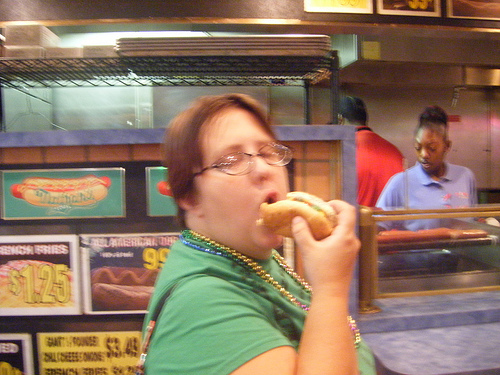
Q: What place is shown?
A: It is a restaurant.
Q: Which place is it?
A: It is a restaurant.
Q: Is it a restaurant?
A: Yes, it is a restaurant.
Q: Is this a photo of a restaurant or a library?
A: It is showing a restaurant.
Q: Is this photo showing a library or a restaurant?
A: It is showing a restaurant.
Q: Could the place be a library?
A: No, it is a restaurant.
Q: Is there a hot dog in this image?
A: Yes, there is a hot dog.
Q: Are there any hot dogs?
A: Yes, there is a hot dog.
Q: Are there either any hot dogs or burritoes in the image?
A: Yes, there is a hot dog.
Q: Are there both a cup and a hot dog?
A: No, there is a hot dog but no cups.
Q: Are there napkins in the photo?
A: No, there are no napkins.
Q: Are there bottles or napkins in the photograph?
A: No, there are no napkins or bottles.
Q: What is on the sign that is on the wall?
A: The hot dog is on the sign.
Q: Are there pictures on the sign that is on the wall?
A: No, there is a hot dog on the sign.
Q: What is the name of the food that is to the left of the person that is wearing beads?
A: The food is a hot dog.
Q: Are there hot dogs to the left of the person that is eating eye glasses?
A: Yes, there is a hot dog to the left of the person.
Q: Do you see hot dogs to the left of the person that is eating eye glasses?
A: Yes, there is a hot dog to the left of the person.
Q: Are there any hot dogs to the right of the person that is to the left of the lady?
A: No, the hot dog is to the left of the person.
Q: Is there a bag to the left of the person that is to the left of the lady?
A: No, there is a hot dog to the left of the person.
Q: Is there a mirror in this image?
A: No, there are no mirrors.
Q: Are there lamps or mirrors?
A: No, there are no mirrors or lamps.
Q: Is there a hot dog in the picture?
A: Yes, there is a hot dog.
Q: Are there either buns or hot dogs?
A: Yes, there is a hot dog.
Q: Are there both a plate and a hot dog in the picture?
A: No, there is a hot dog but no plates.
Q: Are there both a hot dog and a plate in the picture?
A: No, there is a hot dog but no plates.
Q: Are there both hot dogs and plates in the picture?
A: No, there is a hot dog but no plates.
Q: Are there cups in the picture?
A: No, there are no cups.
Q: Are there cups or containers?
A: No, there are no cups or containers.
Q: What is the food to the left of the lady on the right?
A: The food is a hot dog.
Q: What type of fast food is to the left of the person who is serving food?
A: The food is a hot dog.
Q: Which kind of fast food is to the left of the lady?
A: The food is a hot dog.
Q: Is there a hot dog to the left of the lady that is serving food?
A: Yes, there is a hot dog to the left of the lady.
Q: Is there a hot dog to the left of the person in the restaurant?
A: Yes, there is a hot dog to the left of the lady.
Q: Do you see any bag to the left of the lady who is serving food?
A: No, there is a hot dog to the left of the lady.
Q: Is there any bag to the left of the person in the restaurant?
A: No, there is a hot dog to the left of the lady.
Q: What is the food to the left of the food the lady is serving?
A: The food is a hot dog.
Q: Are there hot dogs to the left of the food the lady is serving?
A: Yes, there is a hot dog to the left of the food.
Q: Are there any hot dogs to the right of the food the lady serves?
A: No, the hot dog is to the left of the food.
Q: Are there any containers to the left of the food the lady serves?
A: No, there is a hot dog to the left of the food.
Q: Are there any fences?
A: No, there are no fences.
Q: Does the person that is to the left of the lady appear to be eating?
A: Yes, the person is eating.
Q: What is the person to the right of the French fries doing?
A: The person is eating.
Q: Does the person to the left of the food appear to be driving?
A: No, the person is eating.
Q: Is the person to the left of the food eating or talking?
A: The person is eating.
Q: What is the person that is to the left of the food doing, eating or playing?
A: The person is eating.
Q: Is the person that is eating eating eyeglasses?
A: Yes, the person is eating eyeglasses.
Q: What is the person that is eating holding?
A: The person is holding the hot dog.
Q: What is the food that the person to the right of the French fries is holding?
A: The food is a hot dog.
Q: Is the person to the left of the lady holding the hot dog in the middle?
A: Yes, the person is holding the hot dog.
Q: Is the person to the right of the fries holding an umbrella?
A: No, the person is holding the hot dog.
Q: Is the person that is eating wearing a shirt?
A: Yes, the person is wearing a shirt.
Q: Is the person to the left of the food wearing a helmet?
A: No, the person is wearing a shirt.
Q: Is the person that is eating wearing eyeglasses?
A: Yes, the person is wearing eyeglasses.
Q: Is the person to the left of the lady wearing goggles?
A: No, the person is wearing eyeglasses.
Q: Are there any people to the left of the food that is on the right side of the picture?
A: Yes, there is a person to the left of the food.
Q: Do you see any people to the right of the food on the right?
A: No, the person is to the left of the food.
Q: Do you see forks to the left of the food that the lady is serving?
A: No, there is a person to the left of the food.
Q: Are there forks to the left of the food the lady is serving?
A: No, there is a person to the left of the food.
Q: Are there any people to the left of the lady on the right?
A: Yes, there is a person to the left of the lady.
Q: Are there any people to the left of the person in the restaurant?
A: Yes, there is a person to the left of the lady.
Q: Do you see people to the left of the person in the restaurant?
A: Yes, there is a person to the left of the lady.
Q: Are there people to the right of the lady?
A: No, the person is to the left of the lady.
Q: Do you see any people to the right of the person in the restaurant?
A: No, the person is to the left of the lady.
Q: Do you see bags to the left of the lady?
A: No, there is a person to the left of the lady.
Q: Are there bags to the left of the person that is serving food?
A: No, there is a person to the left of the lady.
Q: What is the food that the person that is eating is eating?
A: The food is a hot dog.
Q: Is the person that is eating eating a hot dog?
A: Yes, the person is eating a hot dog.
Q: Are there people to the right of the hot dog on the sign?
A: Yes, there is a person to the right of the hot dog.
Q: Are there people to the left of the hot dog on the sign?
A: No, the person is to the right of the hot dog.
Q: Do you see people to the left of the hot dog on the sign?
A: No, the person is to the right of the hot dog.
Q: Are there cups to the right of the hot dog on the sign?
A: No, there is a person to the right of the hot dog.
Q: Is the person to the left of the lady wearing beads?
A: Yes, the person is wearing beads.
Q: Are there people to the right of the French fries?
A: Yes, there is a person to the right of the French fries.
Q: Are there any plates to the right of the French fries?
A: No, there is a person to the right of the French fries.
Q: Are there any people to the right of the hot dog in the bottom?
A: Yes, there is a person to the right of the hot dog.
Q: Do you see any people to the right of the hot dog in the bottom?
A: Yes, there is a person to the right of the hot dog.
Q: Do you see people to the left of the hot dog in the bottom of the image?
A: No, the person is to the right of the hot dog.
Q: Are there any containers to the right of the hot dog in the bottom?
A: No, there is a person to the right of the hot dog.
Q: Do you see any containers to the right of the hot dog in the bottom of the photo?
A: No, there is a person to the right of the hot dog.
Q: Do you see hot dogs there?
A: Yes, there is a hot dog.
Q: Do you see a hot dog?
A: Yes, there is a hot dog.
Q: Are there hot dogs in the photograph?
A: Yes, there is a hot dog.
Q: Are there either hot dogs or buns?
A: Yes, there is a hot dog.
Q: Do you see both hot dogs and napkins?
A: No, there is a hot dog but no napkins.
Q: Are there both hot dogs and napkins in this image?
A: No, there is a hot dog but no napkins.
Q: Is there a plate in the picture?
A: No, there are no plates.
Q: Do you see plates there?
A: No, there are no plates.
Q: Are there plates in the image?
A: No, there are no plates.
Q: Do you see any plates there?
A: No, there are no plates.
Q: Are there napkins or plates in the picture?
A: No, there are no plates or napkins.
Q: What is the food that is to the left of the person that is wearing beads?
A: The food is a hot dog.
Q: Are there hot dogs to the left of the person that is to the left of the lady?
A: Yes, there is a hot dog to the left of the person.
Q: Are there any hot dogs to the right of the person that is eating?
A: No, the hot dog is to the left of the person.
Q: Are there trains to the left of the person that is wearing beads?
A: No, there is a hot dog to the left of the person.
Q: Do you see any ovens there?
A: No, there are no ovens.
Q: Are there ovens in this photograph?
A: No, there are no ovens.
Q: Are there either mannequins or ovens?
A: No, there are no ovens or mannequins.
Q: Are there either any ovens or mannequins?
A: No, there are no ovens or mannequins.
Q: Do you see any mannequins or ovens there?
A: No, there are no ovens or mannequins.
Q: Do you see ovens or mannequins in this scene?
A: No, there are no ovens or mannequins.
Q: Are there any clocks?
A: No, there are no clocks.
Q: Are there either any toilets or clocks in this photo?
A: No, there are no clocks or toilets.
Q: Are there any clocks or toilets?
A: No, there are no clocks or toilets.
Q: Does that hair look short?
A: Yes, the hair is short.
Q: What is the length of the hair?
A: The hair is short.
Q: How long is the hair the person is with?
A: The hair is short.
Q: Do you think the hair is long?
A: No, the hair is short.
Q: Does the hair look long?
A: No, the hair is short.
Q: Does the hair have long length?
A: No, the hair is short.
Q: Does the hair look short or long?
A: The hair is short.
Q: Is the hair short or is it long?
A: The hair is short.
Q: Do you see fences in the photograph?
A: No, there are no fences.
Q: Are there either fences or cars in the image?
A: No, there are no fences or cars.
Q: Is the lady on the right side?
A: Yes, the lady is on the right of the image.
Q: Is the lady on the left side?
A: No, the lady is on the right of the image.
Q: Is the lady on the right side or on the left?
A: The lady is on the right of the image.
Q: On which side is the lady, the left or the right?
A: The lady is on the right of the image.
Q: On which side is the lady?
A: The lady is on the right of the image.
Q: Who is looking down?
A: The lady is looking down.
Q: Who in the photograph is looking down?
A: The lady is looking down.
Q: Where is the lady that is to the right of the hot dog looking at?
A: The lady is looking down.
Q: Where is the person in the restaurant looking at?
A: The lady is looking down.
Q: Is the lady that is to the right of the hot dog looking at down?
A: Yes, the lady is looking down.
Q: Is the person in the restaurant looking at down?
A: Yes, the lady is looking down.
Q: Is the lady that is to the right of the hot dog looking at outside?
A: No, the lady is looking down.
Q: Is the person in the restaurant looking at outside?
A: No, the lady is looking down.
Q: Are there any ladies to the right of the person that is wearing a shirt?
A: Yes, there is a lady to the right of the person.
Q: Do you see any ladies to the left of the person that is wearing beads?
A: No, the lady is to the right of the person.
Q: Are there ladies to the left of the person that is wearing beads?
A: No, the lady is to the right of the person.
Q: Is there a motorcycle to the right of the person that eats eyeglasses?
A: No, there is a lady to the right of the person.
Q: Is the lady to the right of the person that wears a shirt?
A: Yes, the lady is to the right of the person.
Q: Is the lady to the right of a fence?
A: No, the lady is to the right of the person.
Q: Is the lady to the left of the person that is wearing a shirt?
A: No, the lady is to the right of the person.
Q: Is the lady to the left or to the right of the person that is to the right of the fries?
A: The lady is to the right of the person.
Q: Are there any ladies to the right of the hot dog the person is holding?
A: Yes, there is a lady to the right of the hot dog.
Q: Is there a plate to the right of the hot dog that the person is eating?
A: No, there is a lady to the right of the hot dog.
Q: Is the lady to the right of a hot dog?
A: Yes, the lady is to the right of a hot dog.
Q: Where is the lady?
A: The lady is in the restaurant.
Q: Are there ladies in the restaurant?
A: Yes, there is a lady in the restaurant.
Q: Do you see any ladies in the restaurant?
A: Yes, there is a lady in the restaurant.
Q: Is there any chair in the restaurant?
A: No, there is a lady in the restaurant.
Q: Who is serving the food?
A: The lady is serving the food.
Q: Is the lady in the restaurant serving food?
A: Yes, the lady is serving food.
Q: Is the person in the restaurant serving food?
A: Yes, the lady is serving food.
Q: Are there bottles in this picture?
A: No, there are no bottles.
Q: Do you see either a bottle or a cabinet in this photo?
A: No, there are no bottles or cabinets.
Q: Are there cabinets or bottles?
A: No, there are no bottles or cabinets.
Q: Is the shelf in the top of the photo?
A: Yes, the shelf is in the top of the image.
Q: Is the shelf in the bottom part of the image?
A: No, the shelf is in the top of the image.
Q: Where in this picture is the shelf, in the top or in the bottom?
A: The shelf is in the top of the image.